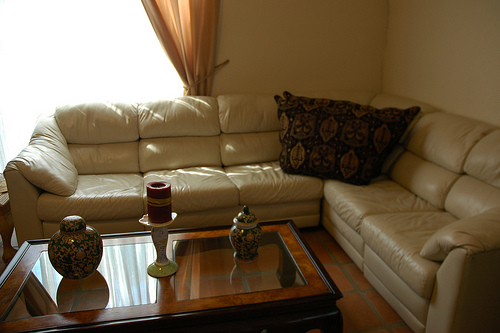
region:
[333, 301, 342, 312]
the floor is wooden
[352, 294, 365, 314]
the floor is wooden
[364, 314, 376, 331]
the floor is wooden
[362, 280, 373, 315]
the floor is wooden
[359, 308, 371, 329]
the floor is wooden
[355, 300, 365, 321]
the floor is wooden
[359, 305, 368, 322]
the floor is wooden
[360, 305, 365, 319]
the floor is wooden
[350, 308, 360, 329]
the floor is wooden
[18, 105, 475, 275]
The sectional is white.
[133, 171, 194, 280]
A candle on the table.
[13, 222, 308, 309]
The table have a glass top.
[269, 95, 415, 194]
A throw pillow on the sofa.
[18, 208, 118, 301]
A vase on the table.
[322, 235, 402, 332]
The flooring is brown tiles.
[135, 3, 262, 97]
The curtain is pulled back from the window.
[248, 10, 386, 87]
The wall is beige.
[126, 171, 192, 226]
The candle is red.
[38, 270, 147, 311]
The reflection of the vase on the glass.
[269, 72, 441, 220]
cushion with pattern on it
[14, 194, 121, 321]
black and gold vase on table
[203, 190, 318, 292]
small black and gold vase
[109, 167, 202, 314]
candle holder on table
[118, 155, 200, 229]
red candle on candle holder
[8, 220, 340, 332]
brown wooden and glass center table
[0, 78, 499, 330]
cream leather couch in living room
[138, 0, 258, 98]
gold curtains hanging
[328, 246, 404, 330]
brown tiled floors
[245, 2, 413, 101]
cream walls in living room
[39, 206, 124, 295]
round vase on a coffee table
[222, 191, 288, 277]
ginger vase on a coffee table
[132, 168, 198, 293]
candle on a candlestick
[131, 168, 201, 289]
candle on a coffee table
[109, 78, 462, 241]
leather sectional sofa in the corner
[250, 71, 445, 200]
two pillows in the corner of a sofa sectional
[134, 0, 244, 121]
tied back curtains on a window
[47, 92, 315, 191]
beige leather sofa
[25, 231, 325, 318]
glass-topped coffee table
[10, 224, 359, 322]
wooden framed coffee table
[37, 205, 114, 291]
small pot with flower design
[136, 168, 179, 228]
small red candle with design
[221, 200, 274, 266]
small floral pot with lid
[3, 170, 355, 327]
decorations on a coffee table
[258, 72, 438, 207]
large fluffy couch pillow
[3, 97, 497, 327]
white leather bisectional sofa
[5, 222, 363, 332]
wood coffee table with glass top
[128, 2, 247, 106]
long tan window dressing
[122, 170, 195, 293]
large red candle in candelabra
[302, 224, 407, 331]
red stone tile flooring